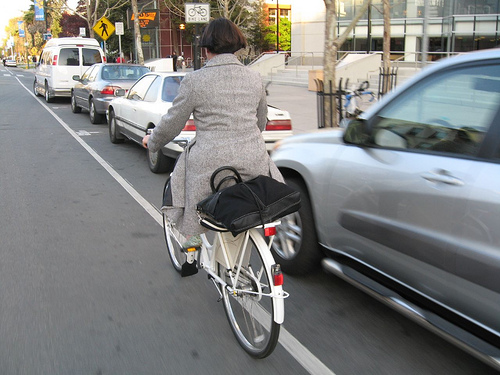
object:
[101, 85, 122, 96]
light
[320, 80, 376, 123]
bike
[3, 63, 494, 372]
road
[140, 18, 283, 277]
person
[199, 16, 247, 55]
hair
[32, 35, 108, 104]
white van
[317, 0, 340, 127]
tree trunk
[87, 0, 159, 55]
tree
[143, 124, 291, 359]
bicycle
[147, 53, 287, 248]
jacket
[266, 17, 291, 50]
leaves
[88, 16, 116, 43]
sign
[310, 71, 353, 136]
black garbage-cans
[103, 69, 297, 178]
car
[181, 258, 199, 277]
shoe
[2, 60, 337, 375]
line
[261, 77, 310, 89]
stairs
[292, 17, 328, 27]
roof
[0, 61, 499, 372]
street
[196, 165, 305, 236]
bag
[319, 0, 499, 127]
building